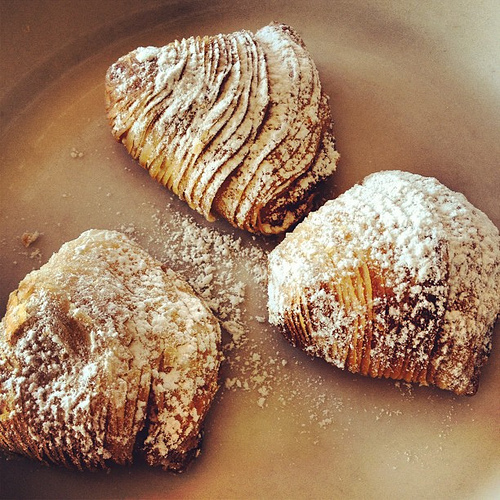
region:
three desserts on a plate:
[4, 19, 498, 483]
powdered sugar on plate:
[238, 348, 281, 409]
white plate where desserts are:
[224, 444, 478, 496]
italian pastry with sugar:
[99, 15, 346, 239]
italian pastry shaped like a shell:
[9, 220, 229, 487]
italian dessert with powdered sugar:
[266, 152, 498, 413]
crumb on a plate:
[19, 226, 45, 251]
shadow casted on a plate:
[5, 461, 201, 498]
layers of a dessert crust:
[334, 275, 379, 300]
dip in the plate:
[12, 55, 79, 112]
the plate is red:
[219, 407, 251, 439]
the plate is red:
[273, 454, 363, 498]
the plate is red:
[279, 390, 350, 481]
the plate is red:
[260, 412, 312, 459]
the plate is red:
[295, 422, 330, 457]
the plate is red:
[316, 457, 364, 494]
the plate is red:
[277, 410, 337, 458]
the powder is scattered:
[85, 153, 271, 453]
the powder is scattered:
[141, 136, 239, 398]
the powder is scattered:
[123, 196, 310, 408]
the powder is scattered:
[103, 148, 208, 306]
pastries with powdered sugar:
[86, 26, 373, 246]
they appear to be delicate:
[104, 30, 366, 238]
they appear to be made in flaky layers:
[243, 154, 494, 425]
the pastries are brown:
[275, 176, 499, 400]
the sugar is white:
[333, 161, 477, 318]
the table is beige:
[274, 404, 491, 476]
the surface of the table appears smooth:
[267, 406, 436, 463]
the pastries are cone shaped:
[103, 20, 345, 245]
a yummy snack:
[19, 226, 232, 493]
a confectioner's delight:
[96, 22, 338, 241]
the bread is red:
[296, 170, 411, 318]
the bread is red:
[337, 227, 422, 362]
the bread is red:
[86, 341, 167, 423]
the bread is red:
[60, 275, 230, 482]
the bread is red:
[86, 380, 183, 458]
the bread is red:
[102, 308, 214, 446]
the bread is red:
[43, 264, 144, 344]